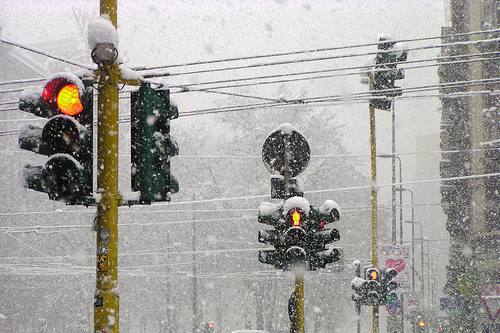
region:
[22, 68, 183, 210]
a street light on a pole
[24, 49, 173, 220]
a street light on a yellow pole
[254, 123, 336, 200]
a round sign on a pole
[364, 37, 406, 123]
a snow covered street light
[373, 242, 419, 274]
a red and white sign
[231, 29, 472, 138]
a snow cover power line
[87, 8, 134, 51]
snow on a yellow pole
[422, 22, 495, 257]
a brown building to the right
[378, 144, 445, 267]
a line od street lights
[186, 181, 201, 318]
a wooden pole near the lines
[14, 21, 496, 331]
Snow is falling around the lights.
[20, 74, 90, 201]
A traffic light on red.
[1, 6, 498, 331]
Snow falling.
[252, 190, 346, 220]
Snow draped on top of a traffic light.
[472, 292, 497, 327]
A red and white sign.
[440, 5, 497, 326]
A tall building.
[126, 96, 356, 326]
A line of trees.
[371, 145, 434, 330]
A row of street lights.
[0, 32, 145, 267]
The side of a building.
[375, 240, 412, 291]
A red heart on a sign.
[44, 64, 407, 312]
Traffic lights functioning during a blizzard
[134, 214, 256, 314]
Flakes of snow blow through the air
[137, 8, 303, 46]
The sky is white and indiscernible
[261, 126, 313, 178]
A circular green sign above the traffic light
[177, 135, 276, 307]
Snow covered trees in the distance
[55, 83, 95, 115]
The traffic light is yellow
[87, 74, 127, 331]
A tall, yellow, metal pole in the street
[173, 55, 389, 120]
Telephone wires hanging above the street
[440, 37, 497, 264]
A tall building by the road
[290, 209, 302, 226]
A yellow light shaped like a person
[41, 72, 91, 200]
an electric traffic signal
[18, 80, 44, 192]
an electric traffic signal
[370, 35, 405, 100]
an electric traffic signal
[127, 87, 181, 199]
an electric traffic signal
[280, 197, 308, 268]
an electric traffic signal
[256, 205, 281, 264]
an electric traffic signal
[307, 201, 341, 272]
an electric traffic signal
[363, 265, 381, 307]
an electric traffic signal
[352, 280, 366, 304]
an electric traffic signal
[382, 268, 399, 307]
an electric traffic signal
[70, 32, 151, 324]
the pole is yellow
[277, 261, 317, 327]
the pole is yellow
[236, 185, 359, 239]
the traffic light is covered with snow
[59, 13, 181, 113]
the traffic light is covered with snow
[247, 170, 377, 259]
the traffic light is covered with snow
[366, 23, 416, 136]
the traffic light is covered with snow